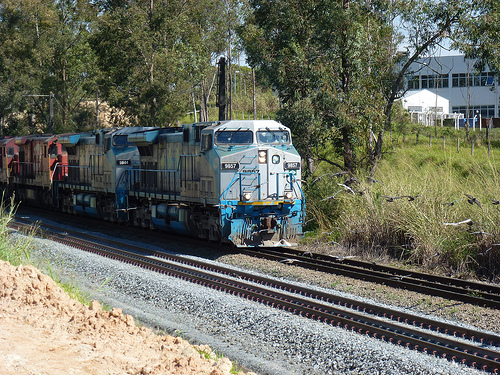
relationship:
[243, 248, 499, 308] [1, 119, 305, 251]
tracks under train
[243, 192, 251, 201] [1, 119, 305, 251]
headlight on train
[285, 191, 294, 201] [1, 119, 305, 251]
headlight on train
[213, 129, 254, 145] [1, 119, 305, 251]
windshield on train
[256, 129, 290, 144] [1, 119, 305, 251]
windshield on train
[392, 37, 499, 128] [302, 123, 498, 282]
building behind grass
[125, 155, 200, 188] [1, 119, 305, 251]
rail on train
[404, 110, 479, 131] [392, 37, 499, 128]
fence in front of building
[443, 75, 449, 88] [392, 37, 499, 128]
window on building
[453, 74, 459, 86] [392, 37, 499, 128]
window on building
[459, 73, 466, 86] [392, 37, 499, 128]
window on building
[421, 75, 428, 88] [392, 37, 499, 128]
window on building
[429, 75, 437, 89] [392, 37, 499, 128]
window on building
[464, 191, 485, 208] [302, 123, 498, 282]
bird over grass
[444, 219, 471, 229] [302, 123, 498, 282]
bird over grass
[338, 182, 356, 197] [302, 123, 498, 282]
bird over grass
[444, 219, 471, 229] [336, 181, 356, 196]
bird over grass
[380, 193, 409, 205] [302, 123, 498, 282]
bird over grass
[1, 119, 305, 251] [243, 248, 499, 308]
train rolling down tracks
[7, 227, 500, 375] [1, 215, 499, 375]
gravel under tracks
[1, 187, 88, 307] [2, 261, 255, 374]
grass on hillside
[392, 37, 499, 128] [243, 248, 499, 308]
building near tracks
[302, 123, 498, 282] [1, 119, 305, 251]
grass beside train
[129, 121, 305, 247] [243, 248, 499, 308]
train engine riding on tracks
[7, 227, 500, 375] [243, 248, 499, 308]
gravel under tracks